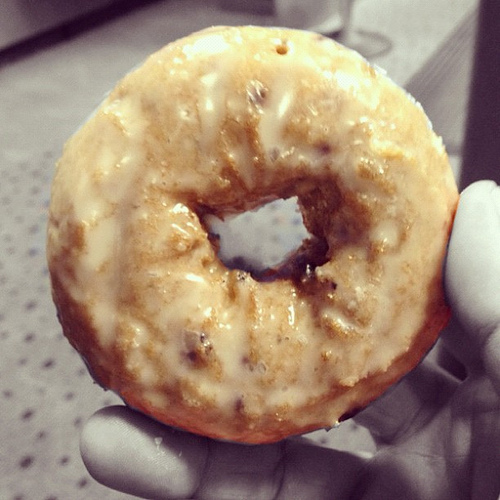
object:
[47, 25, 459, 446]
donut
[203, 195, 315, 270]
hole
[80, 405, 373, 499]
finger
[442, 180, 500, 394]
thumb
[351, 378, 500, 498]
palm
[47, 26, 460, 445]
glaze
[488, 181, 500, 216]
fingernail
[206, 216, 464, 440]
middle finger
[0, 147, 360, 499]
polka dots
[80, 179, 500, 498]
hand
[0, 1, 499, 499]
background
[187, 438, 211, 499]
crease